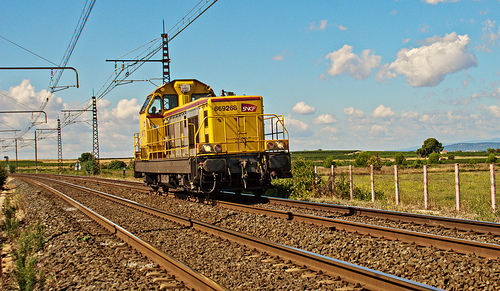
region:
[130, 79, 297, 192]
Train engine sitting on the tracks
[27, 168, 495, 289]
Train tracks.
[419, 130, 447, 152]
Big green tree in the distance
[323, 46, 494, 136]
Big fluffy clouds in the sky.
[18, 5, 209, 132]
Power lines going up the tracks.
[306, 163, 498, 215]
Fence post on the right side of train.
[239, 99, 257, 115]
Small red sign on the engine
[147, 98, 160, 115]
Engineer in the train.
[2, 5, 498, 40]
Blue sky overhead.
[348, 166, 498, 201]
Open meadow to the right of the train.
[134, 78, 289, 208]
the train on the tracks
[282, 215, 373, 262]
gravel on the tracks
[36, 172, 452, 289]
the opposite tracks are empty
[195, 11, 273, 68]
the sky is blue and clear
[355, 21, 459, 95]
the clouds in the sky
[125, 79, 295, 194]
the train is yellow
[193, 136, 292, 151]
the lights on the train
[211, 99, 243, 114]
numbers on the train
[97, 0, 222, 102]
power cables above the train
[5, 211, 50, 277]
weeds growing in the gravel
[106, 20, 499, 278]
a locomotive going down the train tracks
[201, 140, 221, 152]
the headlights on a locomotive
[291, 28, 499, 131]
cumulus clouds in a blue sky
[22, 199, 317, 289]
the rails of a train track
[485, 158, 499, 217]
a wooden fence post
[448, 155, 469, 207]
a wooden fence post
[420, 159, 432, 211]
a wooden fence post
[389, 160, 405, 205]
a wooden fence post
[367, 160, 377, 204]
a wooden fence post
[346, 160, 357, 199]
a wooden fence post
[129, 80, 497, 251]
a locomotive going down the tracks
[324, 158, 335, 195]
a wooden fence post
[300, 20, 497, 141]
several cumulus clouds in a blue sky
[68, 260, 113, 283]
brown rock on ground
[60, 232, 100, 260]
brown rock on ground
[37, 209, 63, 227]
brown rock on ground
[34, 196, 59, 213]
brown rock on ground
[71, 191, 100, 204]
brown rock on ground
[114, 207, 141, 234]
brown rock on ground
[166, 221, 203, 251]
brown rock on ground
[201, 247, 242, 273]
brown rock on ground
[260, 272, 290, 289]
brown rock on ground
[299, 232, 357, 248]
brown rock on ground